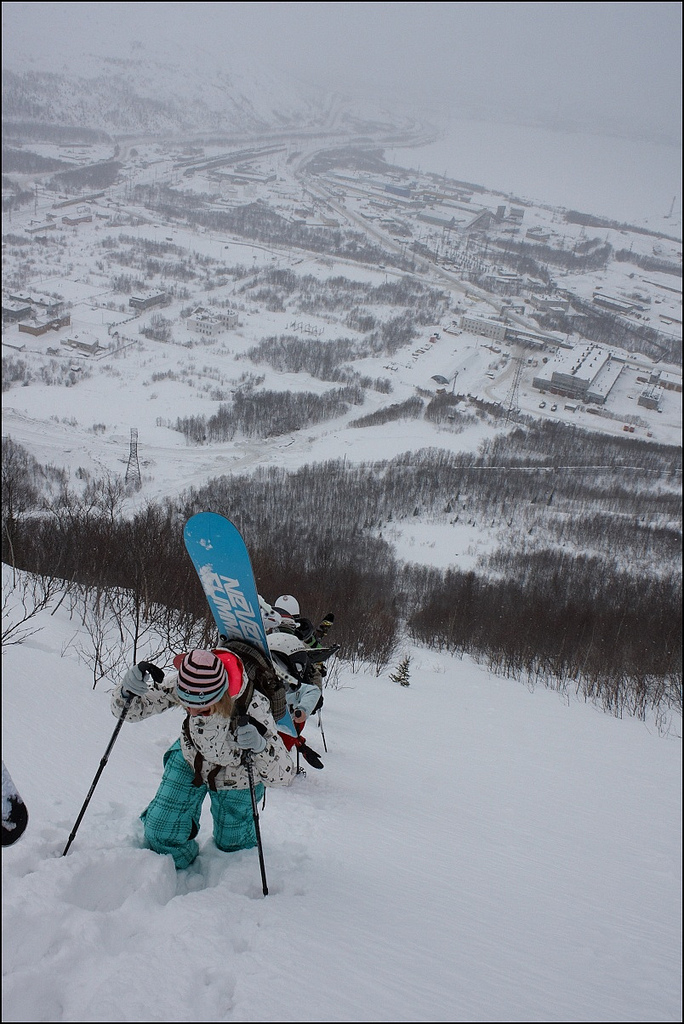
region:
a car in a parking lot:
[547, 401, 553, 409]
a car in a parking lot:
[620, 419, 625, 434]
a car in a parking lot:
[628, 422, 636, 435]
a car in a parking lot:
[425, 332, 440, 342]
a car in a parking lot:
[425, 338, 436, 356]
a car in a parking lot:
[401, 349, 424, 361]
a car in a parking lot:
[483, 368, 493, 379]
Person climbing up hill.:
[87, 504, 296, 861]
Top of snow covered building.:
[533, 333, 624, 409]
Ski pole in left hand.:
[231, 700, 276, 895]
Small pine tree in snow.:
[387, 650, 413, 690]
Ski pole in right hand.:
[60, 654, 162, 863]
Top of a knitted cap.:
[172, 644, 226, 709]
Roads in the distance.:
[173, 102, 426, 196]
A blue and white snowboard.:
[180, 510, 272, 665]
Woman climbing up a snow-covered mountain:
[109, 643, 289, 880]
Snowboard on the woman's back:
[180, 508, 297, 741]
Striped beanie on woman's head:
[171, 643, 230, 708]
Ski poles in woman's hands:
[63, 657, 269, 898]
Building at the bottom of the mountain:
[530, 331, 624, 401]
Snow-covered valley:
[0, 136, 682, 628]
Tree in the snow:
[388, 648, 416, 690]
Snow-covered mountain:
[0, 558, 682, 1021]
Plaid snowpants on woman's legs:
[141, 739, 265, 870]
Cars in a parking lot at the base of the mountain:
[408, 329, 445, 398]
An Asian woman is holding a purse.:
[392, 843, 427, 870]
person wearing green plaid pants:
[136, 641, 259, 870]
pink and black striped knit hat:
[174, 643, 229, 710]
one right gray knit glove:
[114, 654, 154, 697]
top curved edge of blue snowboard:
[176, 507, 271, 645]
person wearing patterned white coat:
[112, 647, 295, 798]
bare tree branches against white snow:
[6, 569, 116, 673]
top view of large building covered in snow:
[526, 326, 628, 407]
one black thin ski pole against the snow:
[36, 669, 128, 858]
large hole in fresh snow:
[61, 841, 170, 927]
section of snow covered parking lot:
[473, 336, 536, 411]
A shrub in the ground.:
[589, 631, 614, 699]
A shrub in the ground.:
[604, 641, 664, 722]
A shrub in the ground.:
[552, 620, 562, 678]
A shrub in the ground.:
[489, 628, 524, 679]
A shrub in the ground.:
[360, 611, 377, 658]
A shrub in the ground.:
[390, 653, 408, 682]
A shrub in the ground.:
[64, 557, 102, 667]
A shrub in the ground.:
[119, 562, 161, 657]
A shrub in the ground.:
[100, 541, 135, 584]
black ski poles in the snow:
[59, 688, 273, 899]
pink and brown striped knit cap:
[175, 651, 226, 707]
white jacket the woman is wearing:
[129, 676, 286, 791]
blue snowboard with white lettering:
[183, 509, 302, 742]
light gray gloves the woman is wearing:
[126, 664, 252, 751]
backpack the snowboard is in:
[222, 641, 287, 732]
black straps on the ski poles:
[139, 649, 268, 742]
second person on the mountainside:
[255, 579, 342, 786]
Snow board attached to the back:
[140, 472, 331, 729]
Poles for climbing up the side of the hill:
[79, 663, 134, 889]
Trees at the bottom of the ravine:
[98, 393, 443, 734]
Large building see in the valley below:
[473, 311, 637, 491]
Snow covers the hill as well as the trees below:
[21, 622, 664, 1006]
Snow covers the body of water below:
[491, 147, 645, 240]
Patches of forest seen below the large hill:
[167, 256, 406, 626]